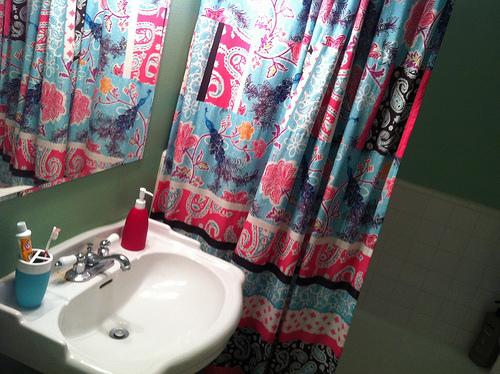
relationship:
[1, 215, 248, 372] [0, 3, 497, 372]
sink in bathroom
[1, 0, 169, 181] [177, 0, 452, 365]
reflection in curtain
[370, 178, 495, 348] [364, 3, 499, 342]
tiles in bathroom wall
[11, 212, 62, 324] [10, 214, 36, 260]
holder holds toothpaste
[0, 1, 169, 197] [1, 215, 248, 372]
mirror over sink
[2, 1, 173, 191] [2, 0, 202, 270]
mirror on wall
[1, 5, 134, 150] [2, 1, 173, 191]
reflection in mirror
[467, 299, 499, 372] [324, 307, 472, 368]
bottle on bathtub